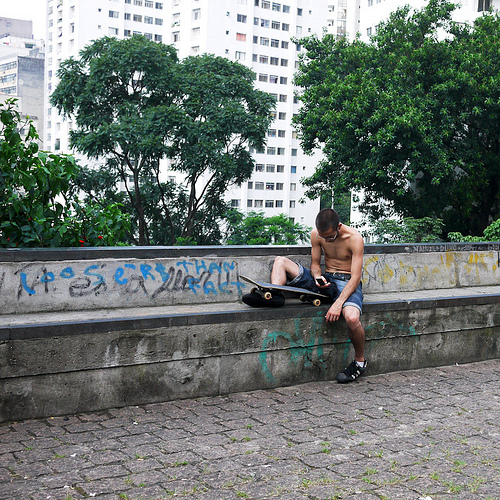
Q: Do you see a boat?
A: No, there are no boats.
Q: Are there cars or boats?
A: No, there are no boats or cars.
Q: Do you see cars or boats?
A: No, there are no boats or cars.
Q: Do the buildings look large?
A: Yes, the buildings are large.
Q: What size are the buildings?
A: The buildings are large.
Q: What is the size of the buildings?
A: The buildings are large.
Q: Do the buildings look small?
A: No, the buildings are large.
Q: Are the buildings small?
A: No, the buildings are large.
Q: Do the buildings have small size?
A: No, the buildings are large.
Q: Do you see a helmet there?
A: No, there are no helmets.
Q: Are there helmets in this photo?
A: No, there are no helmets.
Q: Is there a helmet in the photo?
A: No, there are no helmets.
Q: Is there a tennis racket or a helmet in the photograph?
A: No, there are no helmets or rackets.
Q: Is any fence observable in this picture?
A: No, there are no fences.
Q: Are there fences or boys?
A: No, there are no fences or boys.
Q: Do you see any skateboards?
A: Yes, there is a skateboard.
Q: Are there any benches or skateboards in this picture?
A: Yes, there is a skateboard.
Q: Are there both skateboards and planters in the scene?
A: No, there is a skateboard but no planters.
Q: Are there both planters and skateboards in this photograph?
A: No, there is a skateboard but no planters.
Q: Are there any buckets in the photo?
A: No, there are no buckets.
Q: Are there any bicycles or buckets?
A: No, there are no buckets or bicycles.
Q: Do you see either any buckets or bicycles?
A: No, there are no buckets or bicycles.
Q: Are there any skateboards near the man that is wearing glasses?
A: Yes, there is a skateboard near the man.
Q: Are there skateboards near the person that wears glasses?
A: Yes, there is a skateboard near the man.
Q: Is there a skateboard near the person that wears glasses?
A: Yes, there is a skateboard near the man.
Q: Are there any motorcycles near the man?
A: No, there is a skateboard near the man.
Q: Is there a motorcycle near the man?
A: No, there is a skateboard near the man.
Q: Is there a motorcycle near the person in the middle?
A: No, there is a skateboard near the man.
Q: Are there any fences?
A: No, there are no fences.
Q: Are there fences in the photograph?
A: No, there are no fences.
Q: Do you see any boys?
A: No, there are no boys.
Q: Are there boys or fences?
A: No, there are no boys or fences.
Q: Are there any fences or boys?
A: No, there are no boys or fences.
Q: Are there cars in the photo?
A: No, there are no cars.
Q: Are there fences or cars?
A: No, there are no cars or fences.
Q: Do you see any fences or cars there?
A: No, there are no cars or fences.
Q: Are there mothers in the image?
A: No, there are no mothers.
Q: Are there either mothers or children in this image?
A: No, there are no mothers or children.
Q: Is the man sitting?
A: Yes, the man is sitting.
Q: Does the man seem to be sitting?
A: Yes, the man is sitting.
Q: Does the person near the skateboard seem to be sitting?
A: Yes, the man is sitting.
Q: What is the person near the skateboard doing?
A: The man is sitting.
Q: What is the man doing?
A: The man is sitting.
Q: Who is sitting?
A: The man is sitting.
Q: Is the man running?
A: No, the man is sitting.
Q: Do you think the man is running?
A: No, the man is sitting.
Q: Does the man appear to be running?
A: No, the man is sitting.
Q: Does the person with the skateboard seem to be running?
A: No, the man is sitting.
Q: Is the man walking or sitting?
A: The man is sitting.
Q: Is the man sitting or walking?
A: The man is sitting.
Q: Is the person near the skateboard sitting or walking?
A: The man is sitting.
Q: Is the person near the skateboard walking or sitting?
A: The man is sitting.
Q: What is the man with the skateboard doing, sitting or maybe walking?
A: The man is sitting.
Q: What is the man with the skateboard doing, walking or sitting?
A: The man is sitting.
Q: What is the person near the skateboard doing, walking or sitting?
A: The man is sitting.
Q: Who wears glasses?
A: The man wears glasses.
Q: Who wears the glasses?
A: The man wears glasses.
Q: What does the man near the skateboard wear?
A: The man wears glasses.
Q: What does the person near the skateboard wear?
A: The man wears glasses.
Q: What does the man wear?
A: The man wears glasses.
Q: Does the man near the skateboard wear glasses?
A: Yes, the man wears glasses.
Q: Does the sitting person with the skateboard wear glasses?
A: Yes, the man wears glasses.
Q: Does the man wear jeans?
A: No, the man wears glasses.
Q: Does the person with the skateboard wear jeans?
A: No, the man wears glasses.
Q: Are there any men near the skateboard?
A: Yes, there is a man near the skateboard.